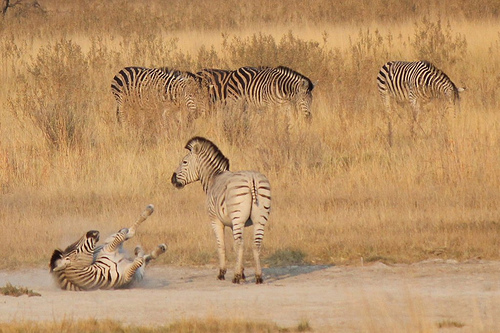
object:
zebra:
[171, 135, 274, 281]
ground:
[0, 2, 500, 247]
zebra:
[48, 203, 172, 291]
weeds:
[281, 117, 452, 180]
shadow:
[243, 243, 336, 285]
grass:
[0, 2, 499, 61]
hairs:
[275, 65, 314, 95]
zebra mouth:
[170, 180, 186, 190]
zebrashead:
[434, 86, 465, 119]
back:
[49, 273, 146, 291]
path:
[0, 260, 500, 333]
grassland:
[269, 127, 500, 256]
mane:
[426, 62, 460, 94]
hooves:
[135, 203, 156, 223]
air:
[0, 134, 163, 203]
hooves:
[231, 268, 243, 284]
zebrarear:
[375, 59, 397, 95]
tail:
[251, 178, 260, 205]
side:
[44, 266, 154, 293]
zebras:
[220, 65, 314, 142]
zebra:
[108, 66, 211, 127]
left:
[0, 3, 48, 333]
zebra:
[374, 57, 463, 128]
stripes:
[224, 192, 250, 201]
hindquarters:
[222, 173, 272, 251]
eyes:
[183, 159, 188, 164]